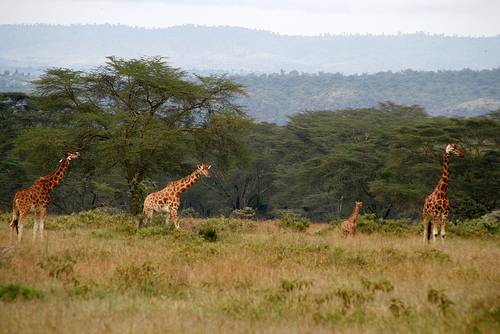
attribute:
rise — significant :
[129, 18, 325, 61]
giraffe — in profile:
[7, 148, 77, 245]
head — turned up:
[58, 148, 82, 165]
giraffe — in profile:
[5, 145, 80, 249]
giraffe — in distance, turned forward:
[338, 196, 365, 236]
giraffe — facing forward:
[420, 143, 465, 246]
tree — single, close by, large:
[21, 54, 258, 214]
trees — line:
[2, 52, 484, 216]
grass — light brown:
[195, 255, 265, 301]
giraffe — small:
[336, 193, 363, 233]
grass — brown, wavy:
[242, 244, 366, 289]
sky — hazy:
[276, 4, 498, 33]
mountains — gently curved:
[205, 61, 498, 119]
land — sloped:
[249, 72, 477, 120]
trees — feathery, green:
[268, 104, 424, 214]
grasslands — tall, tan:
[148, 227, 449, 307]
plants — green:
[386, 242, 447, 265]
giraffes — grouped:
[4, 131, 469, 254]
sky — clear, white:
[4, 5, 496, 28]